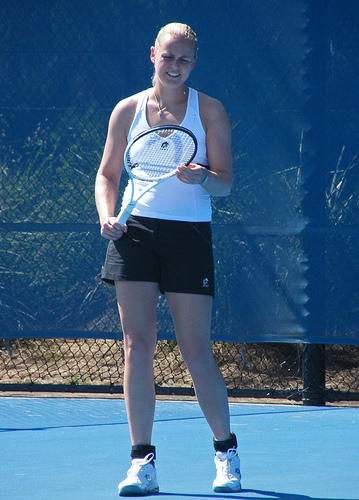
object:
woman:
[94, 21, 241, 492]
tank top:
[116, 85, 213, 221]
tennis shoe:
[116, 452, 159, 497]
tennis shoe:
[212, 447, 242, 492]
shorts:
[100, 208, 216, 301]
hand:
[99, 216, 128, 240]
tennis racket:
[117, 124, 199, 225]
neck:
[154, 76, 184, 104]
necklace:
[152, 86, 186, 118]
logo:
[201, 277, 211, 287]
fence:
[1, 1, 358, 401]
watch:
[200, 169, 211, 187]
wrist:
[200, 166, 210, 191]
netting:
[1, 1, 357, 348]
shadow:
[0, 404, 347, 432]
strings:
[126, 128, 197, 180]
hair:
[151, 22, 199, 88]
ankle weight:
[130, 444, 157, 460]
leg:
[115, 250, 161, 459]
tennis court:
[0, 396, 358, 498]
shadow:
[153, 488, 321, 499]